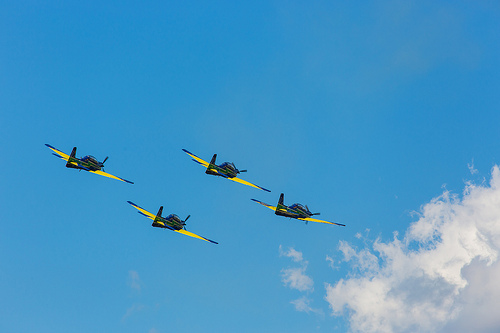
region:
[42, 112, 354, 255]
Four planes in sky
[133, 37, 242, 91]
Blue sky with no clouds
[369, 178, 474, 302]
Fluffy white cloud in blue sky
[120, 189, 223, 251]
Plane with yellow wings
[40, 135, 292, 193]
Two planes flying in sky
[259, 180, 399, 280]
Plane flying toward cloud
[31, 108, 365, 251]
Four planes flying in tight formation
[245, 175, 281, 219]
Two plane wings almost touching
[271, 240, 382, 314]
Small clouds drifting away from large cloud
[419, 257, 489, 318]
Gray and white cloud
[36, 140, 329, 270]
these are jets on air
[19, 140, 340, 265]
the jets are four in number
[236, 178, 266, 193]
the wing is yellow in color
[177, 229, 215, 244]
the wing is sharp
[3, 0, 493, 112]
the sky is blue in color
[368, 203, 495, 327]
the clouds are cotton like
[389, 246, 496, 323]
the clouds are white in color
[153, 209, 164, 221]
the tail is upright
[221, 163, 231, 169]
the body is black in color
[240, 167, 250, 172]
the propeller is moving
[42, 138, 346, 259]
Four planes with yellow and blue flying.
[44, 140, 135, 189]
Plane in upper left position.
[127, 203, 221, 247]
Plane in lower left position.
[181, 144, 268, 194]
Plane in upper right position.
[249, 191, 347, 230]
Plane in lower right position.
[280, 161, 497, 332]
Fluffy white clouds in the sky.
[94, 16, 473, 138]
Sky has clear blue weather.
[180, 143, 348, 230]
Two planes before the pack.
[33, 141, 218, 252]
Two planes holding up the rear.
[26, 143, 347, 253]
Four planes flying high above the clouds.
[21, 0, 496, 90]
this is a sky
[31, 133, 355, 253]
these are jets flying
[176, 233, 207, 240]
the jets has yellow wing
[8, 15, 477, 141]
the sky is blue in colour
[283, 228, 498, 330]
this is a cloud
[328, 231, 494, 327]
the cloud is white in colour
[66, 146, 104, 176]
the body of the jet is black in color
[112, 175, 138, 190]
the jet has a sharp wing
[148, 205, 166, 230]
the jet has sharp tail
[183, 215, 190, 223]
this is a propeller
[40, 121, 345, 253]
four jets in flight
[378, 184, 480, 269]
white cloud in sky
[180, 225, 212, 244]
yellow wing on plane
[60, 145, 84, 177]
tail on back of plane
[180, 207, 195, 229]
propeller on front of plane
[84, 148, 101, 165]
dome over plane cockpit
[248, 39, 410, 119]
clear blue daytime sky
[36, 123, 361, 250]
planes flying in formation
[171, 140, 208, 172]
wing tilted upward in sky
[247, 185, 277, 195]
dark tip of wing